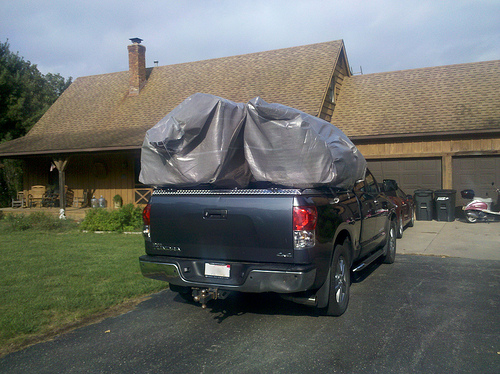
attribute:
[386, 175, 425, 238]
car — red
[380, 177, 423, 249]
car — parked 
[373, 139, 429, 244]
car — dark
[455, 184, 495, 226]
motorcycle — grey , maroon , parked 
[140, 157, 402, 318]
truck — parked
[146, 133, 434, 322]
truck — blue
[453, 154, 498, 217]
door — brown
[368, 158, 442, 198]
door — brown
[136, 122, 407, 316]
truck — navy blue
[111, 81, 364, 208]
cargo — plastic, gray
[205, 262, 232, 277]
license — white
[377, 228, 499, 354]
driveway — dark gray, paved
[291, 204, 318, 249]
brakelights — red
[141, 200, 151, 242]
brakelights — red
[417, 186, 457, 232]
trash cans — green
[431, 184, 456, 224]
cans — standing 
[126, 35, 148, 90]
chimney — bricked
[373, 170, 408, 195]
mirror — black side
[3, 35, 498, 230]
house — wood, paneled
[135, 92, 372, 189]
tarp — gray, grey 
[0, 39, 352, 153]
roof — gray, tiled, bricked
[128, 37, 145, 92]
chimney — red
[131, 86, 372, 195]
furniture — covered 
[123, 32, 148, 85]
chimney — brick 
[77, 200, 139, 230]
bushes — growing 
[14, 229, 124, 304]
grass — green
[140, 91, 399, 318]
truck — parked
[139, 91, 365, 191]
object — covered , big